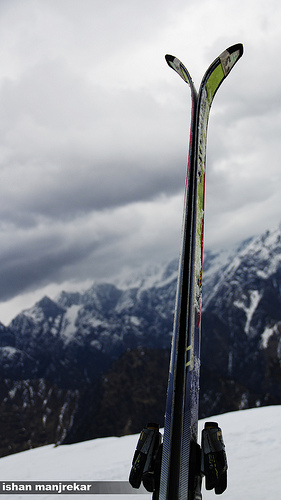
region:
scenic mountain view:
[12, 278, 104, 389]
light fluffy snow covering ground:
[3, 458, 102, 488]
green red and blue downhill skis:
[167, 43, 219, 427]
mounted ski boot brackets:
[116, 401, 206, 495]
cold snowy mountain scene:
[2, 285, 277, 407]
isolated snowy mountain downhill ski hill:
[0, 358, 56, 457]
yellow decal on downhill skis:
[195, 261, 218, 320]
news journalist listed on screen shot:
[3, 462, 98, 498]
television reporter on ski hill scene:
[104, 468, 124, 498]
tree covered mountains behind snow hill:
[222, 352, 276, 461]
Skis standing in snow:
[127, 43, 245, 498]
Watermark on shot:
[0, 480, 145, 494]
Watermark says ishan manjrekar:
[0, 481, 130, 492]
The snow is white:
[2, 405, 279, 498]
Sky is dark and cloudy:
[1, 0, 280, 324]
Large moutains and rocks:
[1, 227, 280, 457]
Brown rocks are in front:
[1, 347, 279, 458]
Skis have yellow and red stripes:
[164, 43, 243, 326]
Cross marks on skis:
[156, 406, 199, 499]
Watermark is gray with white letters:
[0, 481, 140, 493]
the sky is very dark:
[40, 188, 147, 270]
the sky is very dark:
[51, 165, 139, 249]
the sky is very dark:
[67, 150, 181, 291]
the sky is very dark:
[53, 165, 236, 317]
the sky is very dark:
[50, 132, 140, 212]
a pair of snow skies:
[148, 56, 210, 373]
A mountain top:
[18, 271, 134, 395]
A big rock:
[66, 361, 235, 415]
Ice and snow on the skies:
[183, 338, 201, 425]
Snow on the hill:
[19, 455, 99, 473]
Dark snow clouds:
[10, 211, 133, 282]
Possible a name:
[2, 477, 98, 497]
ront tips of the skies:
[150, 33, 244, 117]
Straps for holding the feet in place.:
[125, 413, 220, 484]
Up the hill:
[232, 408, 274, 458]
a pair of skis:
[154, 231, 223, 432]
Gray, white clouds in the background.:
[47, 116, 173, 282]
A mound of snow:
[45, 457, 234, 483]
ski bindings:
[201, 408, 234, 491]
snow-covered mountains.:
[33, 285, 139, 350]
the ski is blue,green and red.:
[178, 247, 219, 407]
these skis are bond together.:
[153, 352, 214, 494]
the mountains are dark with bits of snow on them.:
[63, 271, 230, 341]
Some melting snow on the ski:
[186, 356, 202, 410]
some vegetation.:
[112, 360, 161, 431]